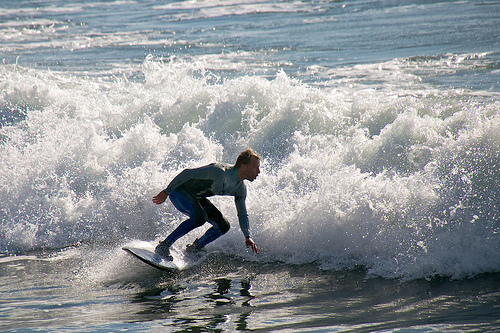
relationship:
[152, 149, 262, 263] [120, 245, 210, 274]
man on board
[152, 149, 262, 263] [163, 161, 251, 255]
man wearing suit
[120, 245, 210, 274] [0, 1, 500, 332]
board in water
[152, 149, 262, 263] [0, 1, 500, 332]
man on water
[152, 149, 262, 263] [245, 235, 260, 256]
man has hand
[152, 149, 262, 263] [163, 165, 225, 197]
man has arm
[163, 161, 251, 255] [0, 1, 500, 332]
suit over water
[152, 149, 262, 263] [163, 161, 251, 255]
man in suit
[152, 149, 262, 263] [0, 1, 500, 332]
man in water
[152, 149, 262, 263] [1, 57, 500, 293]
man on wave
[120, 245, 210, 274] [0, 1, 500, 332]
board on water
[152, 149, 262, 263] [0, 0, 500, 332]
man in ocean